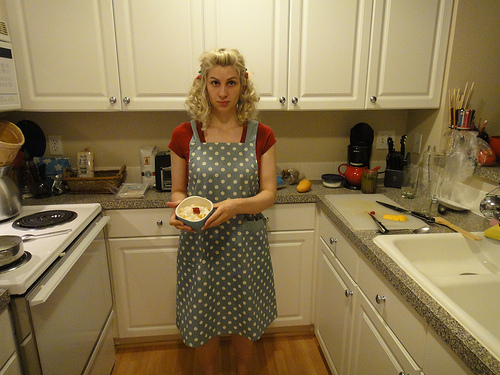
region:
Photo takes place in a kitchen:
[10, 2, 488, 367]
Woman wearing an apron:
[143, 63, 305, 358]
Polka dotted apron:
[153, 108, 298, 350]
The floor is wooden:
[87, 323, 349, 371]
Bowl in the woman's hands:
[162, 180, 224, 234]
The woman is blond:
[165, 41, 276, 136]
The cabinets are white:
[59, 18, 463, 369]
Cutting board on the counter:
[310, 179, 439, 236]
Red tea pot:
[335, 161, 378, 185]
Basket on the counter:
[53, 142, 139, 195]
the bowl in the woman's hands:
[175, 194, 217, 231]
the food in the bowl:
[177, 204, 207, 221]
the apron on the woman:
[177, 117, 278, 347]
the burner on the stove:
[12, 210, 77, 229]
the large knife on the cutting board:
[374, 198, 435, 222]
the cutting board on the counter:
[325, 193, 430, 230]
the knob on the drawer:
[327, 234, 337, 244]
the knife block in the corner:
[382, 135, 407, 187]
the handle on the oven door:
[27, 214, 112, 307]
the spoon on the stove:
[20, 228, 71, 241]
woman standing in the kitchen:
[117, 34, 324, 349]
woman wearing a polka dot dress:
[130, 40, 302, 342]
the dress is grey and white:
[130, 39, 306, 348]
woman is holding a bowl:
[153, 174, 251, 250]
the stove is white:
[10, 194, 124, 334]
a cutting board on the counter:
[320, 170, 433, 250]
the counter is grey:
[349, 175, 457, 232]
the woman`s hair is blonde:
[152, 53, 272, 130]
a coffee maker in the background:
[326, 113, 381, 183]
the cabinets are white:
[19, 0, 416, 116]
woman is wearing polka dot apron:
[165, 47, 275, 367]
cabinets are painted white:
[0, 0, 470, 370]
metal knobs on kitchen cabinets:
[107, 95, 377, 300]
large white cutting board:
[325, 195, 430, 232]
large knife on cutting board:
[374, 197, 434, 225]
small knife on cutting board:
[368, 211, 386, 236]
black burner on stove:
[12, 205, 78, 229]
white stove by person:
[1, 203, 116, 372]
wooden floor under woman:
[109, 325, 334, 373]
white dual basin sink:
[373, 229, 498, 366]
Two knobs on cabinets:
[106, 88, 136, 113]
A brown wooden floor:
[110, 330, 330, 373]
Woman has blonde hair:
[185, 43, 263, 133]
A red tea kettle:
[336, 158, 383, 190]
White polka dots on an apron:
[172, 118, 281, 351]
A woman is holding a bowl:
[162, 43, 282, 239]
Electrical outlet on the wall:
[45, 131, 68, 159]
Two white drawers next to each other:
[316, 208, 432, 372]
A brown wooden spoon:
[429, 209, 485, 248]